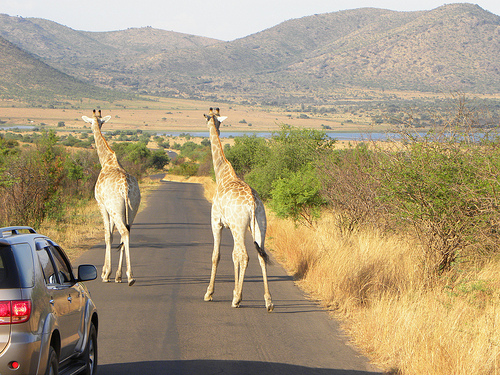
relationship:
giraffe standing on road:
[201, 106, 277, 313] [70, 177, 381, 373]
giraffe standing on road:
[80, 106, 138, 286] [70, 177, 381, 373]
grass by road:
[383, 210, 464, 354] [70, 177, 381, 373]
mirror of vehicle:
[74, 263, 99, 281] [0, 222, 100, 374]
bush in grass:
[262, 165, 321, 218] [167, 134, 499, 374]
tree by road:
[316, 158, 383, 243] [67, 177, 380, 374]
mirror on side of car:
[74, 263, 99, 281] [0, 225, 97, 374]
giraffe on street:
[80, 106, 144, 285] [98, 174, 313, 374]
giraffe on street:
[201, 106, 277, 313] [98, 174, 313, 374]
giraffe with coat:
[190, 99, 272, 319] [155, 80, 375, 340]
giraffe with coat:
[80, 106, 144, 285] [155, 80, 375, 340]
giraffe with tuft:
[201, 106, 277, 313] [251, 231, 277, 269]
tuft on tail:
[251, 231, 277, 269] [234, 188, 282, 289]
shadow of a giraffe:
[264, 260, 318, 294] [201, 106, 277, 313]